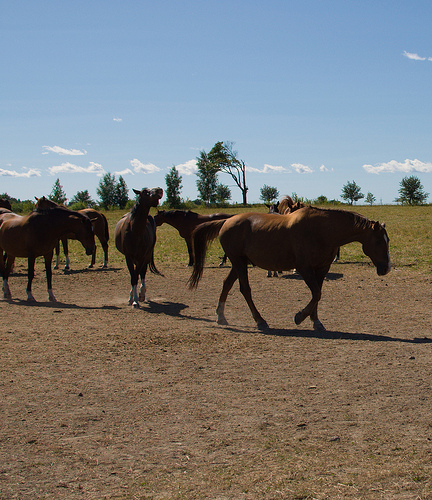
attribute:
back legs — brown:
[215, 256, 273, 334]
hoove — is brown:
[298, 306, 347, 347]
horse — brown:
[181, 164, 414, 355]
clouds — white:
[243, 140, 431, 191]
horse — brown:
[29, 191, 111, 268]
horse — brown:
[150, 208, 243, 265]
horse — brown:
[212, 206, 393, 329]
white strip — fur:
[382, 232, 388, 242]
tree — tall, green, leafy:
[162, 167, 184, 205]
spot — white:
[382, 230, 389, 242]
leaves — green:
[398, 173, 412, 193]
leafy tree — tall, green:
[195, 140, 225, 207]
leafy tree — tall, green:
[168, 163, 184, 208]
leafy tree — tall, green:
[339, 177, 363, 204]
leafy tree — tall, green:
[400, 174, 421, 205]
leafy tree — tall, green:
[49, 179, 63, 201]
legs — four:
[214, 268, 328, 335]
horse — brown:
[186, 210, 392, 334]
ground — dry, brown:
[100, 367, 160, 410]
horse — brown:
[1, 209, 98, 302]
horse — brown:
[115, 185, 169, 300]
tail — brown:
[183, 208, 226, 293]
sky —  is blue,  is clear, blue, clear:
[1, 1, 429, 200]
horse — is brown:
[181, 194, 400, 338]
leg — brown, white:
[238, 269, 267, 324]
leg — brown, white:
[214, 264, 238, 320]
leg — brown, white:
[297, 272, 322, 312]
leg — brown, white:
[310, 310, 318, 322]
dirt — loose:
[2, 267, 429, 498]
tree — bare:
[209, 139, 247, 204]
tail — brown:
[180, 222, 212, 278]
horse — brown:
[114, 182, 163, 310]